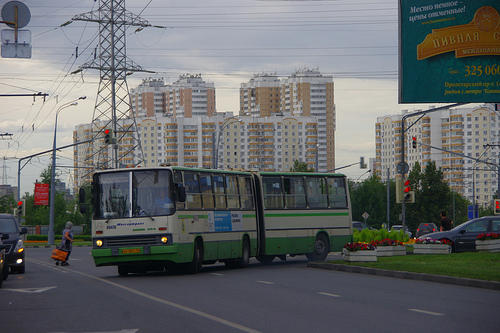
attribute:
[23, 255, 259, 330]
line — white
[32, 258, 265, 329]
line — white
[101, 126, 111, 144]
traffic light — red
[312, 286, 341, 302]
lines — white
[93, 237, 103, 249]
headlight — on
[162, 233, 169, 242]
headlight — on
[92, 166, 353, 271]
bus — green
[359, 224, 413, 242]
flowers — yellow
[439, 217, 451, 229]
shirt — black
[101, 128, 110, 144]
traffic light — red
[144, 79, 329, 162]
buildings — tan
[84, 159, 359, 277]
bus — green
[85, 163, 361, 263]
"white and green bus — white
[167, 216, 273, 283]
green bus — white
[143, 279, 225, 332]
line on the pavement — white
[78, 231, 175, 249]
bus headlights — on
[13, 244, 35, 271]
vehicle headlights — on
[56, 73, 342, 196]
buildings — brown , white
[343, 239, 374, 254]
flowers are red — red 